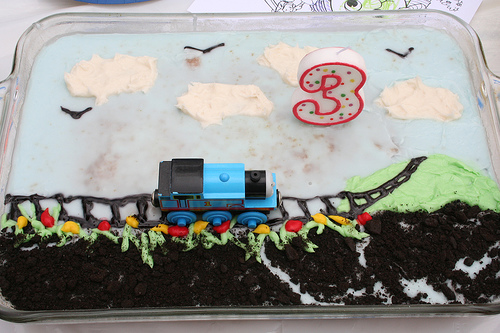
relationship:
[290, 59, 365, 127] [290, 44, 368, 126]
outline accentuating candle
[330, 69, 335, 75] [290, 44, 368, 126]
dot adorning candle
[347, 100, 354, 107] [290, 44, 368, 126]
dot adorning candle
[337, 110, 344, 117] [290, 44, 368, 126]
dot adorning candle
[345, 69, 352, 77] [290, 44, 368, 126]
dot adorning candle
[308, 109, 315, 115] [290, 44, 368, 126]
dot adorning candle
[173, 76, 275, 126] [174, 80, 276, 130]
icing forming cloud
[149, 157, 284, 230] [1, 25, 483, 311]
train sitting on top of cake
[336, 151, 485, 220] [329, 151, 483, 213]
icing forming grass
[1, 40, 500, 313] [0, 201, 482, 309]
cake forming dirt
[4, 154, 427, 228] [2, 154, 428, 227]
icing forming train track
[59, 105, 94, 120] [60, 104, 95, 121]
icing forming bird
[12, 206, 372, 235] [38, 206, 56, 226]
icing forming flower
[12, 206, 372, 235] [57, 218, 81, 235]
icing forming flower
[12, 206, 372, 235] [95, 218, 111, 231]
icing forming flower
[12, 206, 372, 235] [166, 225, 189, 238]
icing forming flower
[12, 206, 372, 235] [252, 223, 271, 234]
icing forming flower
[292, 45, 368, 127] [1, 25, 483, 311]
candle stuck into cake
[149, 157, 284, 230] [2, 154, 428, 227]
train sitting on top of train track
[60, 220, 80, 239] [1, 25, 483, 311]
icing decorating cake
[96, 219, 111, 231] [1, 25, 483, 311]
icing decorating cake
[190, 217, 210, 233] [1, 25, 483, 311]
icing decorating cake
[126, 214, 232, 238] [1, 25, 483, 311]
icing decorating cake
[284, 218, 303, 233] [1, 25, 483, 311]
icing decorating cake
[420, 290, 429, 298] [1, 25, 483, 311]
oreo decorating cake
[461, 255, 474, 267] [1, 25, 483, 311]
oreo decorating cake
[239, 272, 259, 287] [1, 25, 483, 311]
oreo decorating cake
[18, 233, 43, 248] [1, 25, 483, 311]
oreo decorating cake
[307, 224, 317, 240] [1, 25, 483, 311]
oreo decorating cake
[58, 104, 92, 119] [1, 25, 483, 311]
bird decorating cake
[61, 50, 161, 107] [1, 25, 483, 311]
cloud adorning cake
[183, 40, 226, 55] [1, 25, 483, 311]
bird adorning cake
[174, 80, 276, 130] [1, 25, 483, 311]
cloud adorning cake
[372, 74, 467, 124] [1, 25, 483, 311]
cloud adorning cake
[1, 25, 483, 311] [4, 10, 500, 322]
cake sitting inside cake pan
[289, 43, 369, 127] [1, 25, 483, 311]
number stuck into cake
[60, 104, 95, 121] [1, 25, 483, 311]
bird adorning cake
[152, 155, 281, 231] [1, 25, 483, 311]
tank engine on cake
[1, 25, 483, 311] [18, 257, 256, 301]
cake contains cookie crumbs